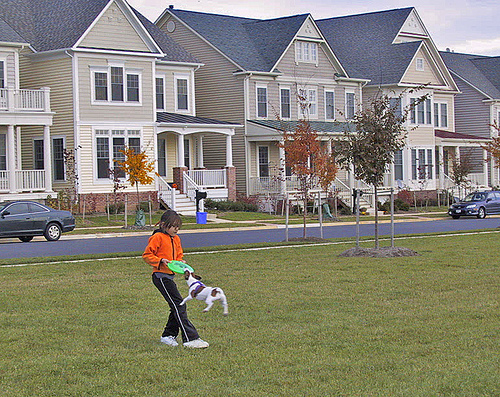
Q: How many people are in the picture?
A: 1.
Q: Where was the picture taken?
A: In a neighborhood.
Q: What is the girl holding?
A: A Frisbee.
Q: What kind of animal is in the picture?
A: A dog.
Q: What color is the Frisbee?
A: Green.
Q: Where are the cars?
A: On a street.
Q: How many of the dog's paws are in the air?
A: Four.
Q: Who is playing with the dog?
A: Young girl.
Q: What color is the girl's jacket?
A: Orange.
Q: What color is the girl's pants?
A: Black.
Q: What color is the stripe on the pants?
A: White.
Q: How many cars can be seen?
A: Two.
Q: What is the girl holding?
A: Frisbee.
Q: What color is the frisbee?
A: Green.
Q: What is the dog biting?
A: A frisbee.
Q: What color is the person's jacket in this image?
A: Orange.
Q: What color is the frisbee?
A: Green.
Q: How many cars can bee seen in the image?
A: 2.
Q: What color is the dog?
A: White and brown.